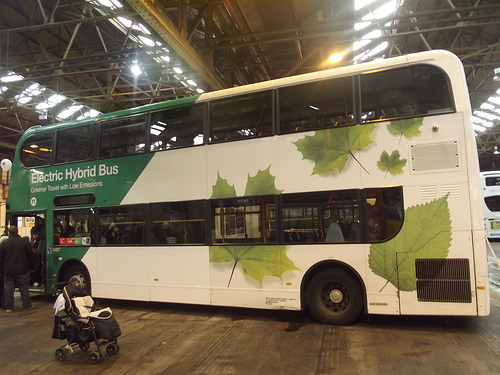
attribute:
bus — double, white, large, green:
[5, 48, 490, 328]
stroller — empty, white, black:
[51, 280, 120, 364]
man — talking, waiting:
[2, 227, 34, 314]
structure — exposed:
[1, 1, 500, 173]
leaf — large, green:
[367, 192, 451, 293]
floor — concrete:
[3, 290, 500, 375]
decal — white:
[30, 160, 120, 184]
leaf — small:
[377, 148, 408, 182]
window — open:
[98, 114, 148, 160]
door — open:
[6, 210, 48, 292]